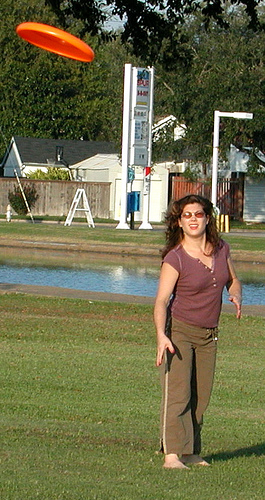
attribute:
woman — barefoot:
[141, 179, 259, 495]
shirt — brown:
[159, 251, 230, 335]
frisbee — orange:
[11, 14, 111, 73]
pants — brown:
[163, 321, 214, 453]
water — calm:
[17, 251, 149, 291]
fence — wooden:
[18, 172, 67, 217]